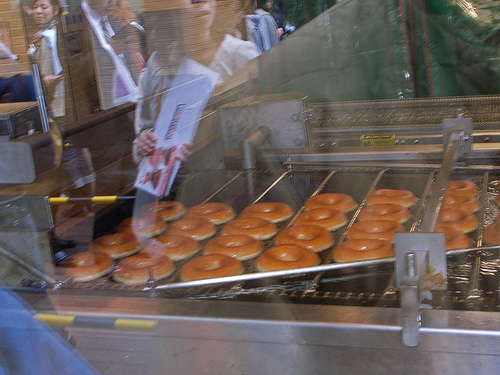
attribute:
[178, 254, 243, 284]
donut — glazed, ready, brown, fried, round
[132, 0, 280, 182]
lady — looking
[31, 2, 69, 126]
person — reflected, standing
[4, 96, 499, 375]
machine — large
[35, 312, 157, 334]
handle — yellow, black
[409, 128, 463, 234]
bar — metal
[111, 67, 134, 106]
triangle — purple